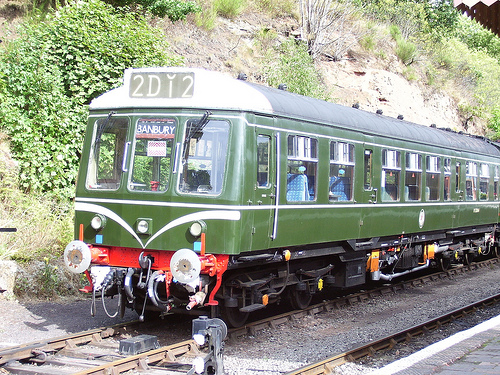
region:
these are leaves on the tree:
[5, 42, 60, 91]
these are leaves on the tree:
[20, 88, 69, 142]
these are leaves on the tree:
[33, 140, 76, 179]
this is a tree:
[253, 35, 335, 110]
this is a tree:
[3, 39, 87, 206]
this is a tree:
[287, 0, 354, 77]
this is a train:
[90, 66, 497, 318]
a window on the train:
[247, 126, 277, 200]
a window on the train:
[281, 130, 321, 162]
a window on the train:
[334, 135, 361, 168]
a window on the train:
[375, 140, 402, 174]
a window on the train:
[400, 146, 417, 173]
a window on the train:
[423, 148, 443, 172]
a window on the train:
[441, 153, 456, 177]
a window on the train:
[461, 158, 486, 177]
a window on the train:
[328, 163, 351, 208]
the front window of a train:
[93, 119, 126, 184]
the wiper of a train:
[178, 114, 212, 156]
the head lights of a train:
[86, 215, 203, 240]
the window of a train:
[289, 129, 316, 199]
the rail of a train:
[28, 335, 160, 372]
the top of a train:
[256, 95, 430, 132]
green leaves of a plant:
[21, 25, 119, 94]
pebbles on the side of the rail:
[259, 342, 314, 367]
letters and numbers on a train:
[124, 74, 200, 96]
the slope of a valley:
[335, 3, 407, 118]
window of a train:
[176, 115, 240, 200]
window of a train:
[123, 120, 196, 192]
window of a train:
[77, 103, 147, 190]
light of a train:
[88, 208, 123, 228]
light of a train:
[129, 214, 159, 233]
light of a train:
[185, 209, 208, 236]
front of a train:
[65, 245, 229, 307]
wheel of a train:
[214, 279, 277, 331]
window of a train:
[274, 135, 334, 215]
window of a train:
[328, 140, 368, 211]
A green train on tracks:
[64, 43, 498, 345]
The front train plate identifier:
[119, 69, 199, 104]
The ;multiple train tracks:
[0, 252, 499, 373]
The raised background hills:
[0, 0, 499, 300]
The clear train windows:
[86, 114, 498, 206]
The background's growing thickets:
[0, 0, 498, 293]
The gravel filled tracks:
[1, 248, 498, 373]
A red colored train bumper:
[64, 244, 228, 301]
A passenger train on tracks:
[0, 0, 498, 374]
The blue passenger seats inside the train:
[279, 159, 498, 207]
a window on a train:
[85, 115, 123, 183]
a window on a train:
[126, 112, 178, 196]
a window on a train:
[178, 117, 227, 199]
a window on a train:
[251, 130, 275, 187]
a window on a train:
[283, 132, 315, 203]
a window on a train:
[328, 133, 356, 197]